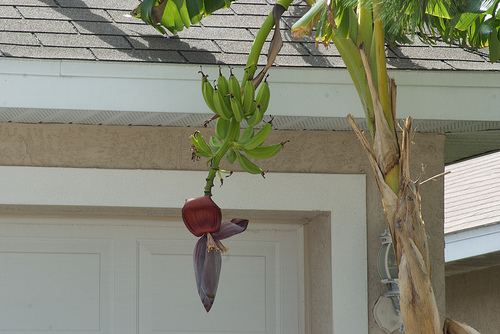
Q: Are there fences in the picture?
A: No, there are no fences.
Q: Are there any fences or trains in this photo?
A: No, there are no fences or trains.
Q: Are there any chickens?
A: No, there are no chickens.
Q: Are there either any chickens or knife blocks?
A: No, there are no chickens or knife blocks.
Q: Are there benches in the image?
A: No, there are no benches.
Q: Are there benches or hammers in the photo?
A: No, there are no benches or hammers.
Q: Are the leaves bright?
A: Yes, the leaves are bright.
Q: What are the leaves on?
A: The leaves are on the tree.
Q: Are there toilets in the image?
A: No, there are no toilets.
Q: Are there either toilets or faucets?
A: No, there are no toilets or faucets.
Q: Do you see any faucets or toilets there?
A: No, there are no toilets or faucets.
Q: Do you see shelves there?
A: No, there are no shelves.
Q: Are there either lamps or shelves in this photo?
A: No, there are no shelves or lamps.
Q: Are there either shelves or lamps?
A: No, there are no shelves or lamps.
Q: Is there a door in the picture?
A: Yes, there is a door.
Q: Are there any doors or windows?
A: Yes, there is a door.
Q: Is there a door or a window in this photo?
A: Yes, there is a door.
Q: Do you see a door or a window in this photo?
A: Yes, there is a door.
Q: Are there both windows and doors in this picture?
A: No, there is a door but no windows.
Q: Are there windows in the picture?
A: No, there are no windows.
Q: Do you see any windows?
A: No, there are no windows.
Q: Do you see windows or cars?
A: No, there are no windows or cars.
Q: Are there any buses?
A: No, there are no buses.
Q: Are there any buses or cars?
A: No, there are no buses or cars.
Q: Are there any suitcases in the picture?
A: No, there are no suitcases.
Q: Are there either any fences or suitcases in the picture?
A: No, there are no suitcases or fences.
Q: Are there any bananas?
A: Yes, there are bananas.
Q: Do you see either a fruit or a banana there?
A: Yes, there are bananas.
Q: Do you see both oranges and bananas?
A: No, there are bananas but no oranges.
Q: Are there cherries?
A: No, there are no cherries.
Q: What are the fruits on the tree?
A: The fruits are bananas.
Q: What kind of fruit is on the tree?
A: The fruits are bananas.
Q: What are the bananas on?
A: The bananas are on the tree.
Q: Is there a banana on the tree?
A: Yes, there are bananas on the tree.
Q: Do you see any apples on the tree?
A: No, there are bananas on the tree.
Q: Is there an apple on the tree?
A: No, there are bananas on the tree.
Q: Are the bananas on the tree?
A: Yes, the bananas are on the tree.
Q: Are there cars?
A: No, there are no cars.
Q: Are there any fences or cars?
A: No, there are no cars or fences.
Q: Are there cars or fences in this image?
A: No, there are no cars or fences.